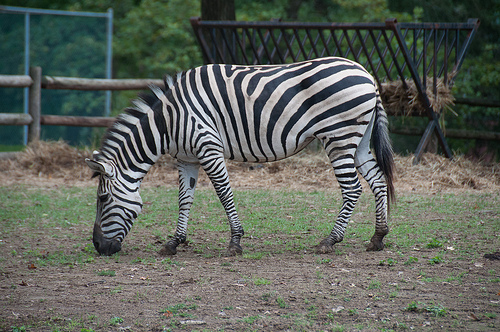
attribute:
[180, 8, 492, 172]
hay dispenser — metal, black, full, brown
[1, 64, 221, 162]
fence — wooden, enclosing, partition, linked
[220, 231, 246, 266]
hoof — dirty, grey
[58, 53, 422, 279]
zebra — black, medium sized, white, eating, dirty, grazing, striped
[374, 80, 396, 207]
tail — spiky, black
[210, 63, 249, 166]
stripe — black, white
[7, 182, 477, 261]
grass — scrubby, dry, loose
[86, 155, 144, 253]
head — down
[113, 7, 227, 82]
bush — green, behind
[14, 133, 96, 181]
pile — gray, hay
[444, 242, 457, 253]
leaf — dead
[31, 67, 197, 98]
pole — wooden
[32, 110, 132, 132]
pole — wooden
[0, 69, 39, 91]
pole — wooden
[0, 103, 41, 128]
pole — wooden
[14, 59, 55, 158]
pole — wooden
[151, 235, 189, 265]
hoof — dirty, grey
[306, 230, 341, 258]
hoof — dirty, grey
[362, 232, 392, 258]
hoof — dirty, grey